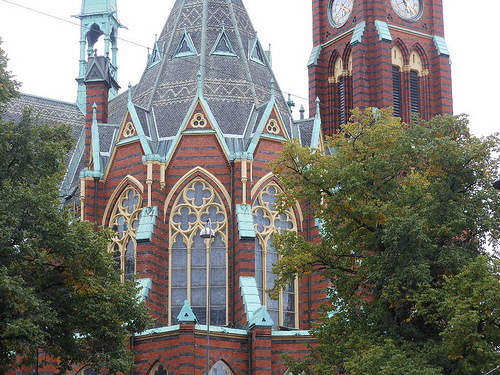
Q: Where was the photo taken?
A: It was taken at the church.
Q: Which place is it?
A: It is a church.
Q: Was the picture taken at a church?
A: Yes, it was taken in a church.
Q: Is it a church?
A: Yes, it is a church.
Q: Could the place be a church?
A: Yes, it is a church.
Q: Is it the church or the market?
A: It is the church.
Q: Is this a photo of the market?
A: No, the picture is showing the church.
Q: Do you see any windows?
A: Yes, there is a window.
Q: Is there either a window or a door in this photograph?
A: Yes, there is a window.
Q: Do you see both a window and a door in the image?
A: No, there is a window but no doors.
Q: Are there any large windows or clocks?
A: Yes, there is a large window.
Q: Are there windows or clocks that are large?
A: Yes, the window is large.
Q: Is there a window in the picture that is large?
A: Yes, there is a large window.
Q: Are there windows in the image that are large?
A: Yes, there is a window that is large.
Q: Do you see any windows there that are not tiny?
A: Yes, there is a large window.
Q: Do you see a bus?
A: No, there are no buses.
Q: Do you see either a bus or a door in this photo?
A: No, there are no buses or doors.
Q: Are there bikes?
A: No, there are no bikes.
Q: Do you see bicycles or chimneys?
A: No, there are no bicycles or chimneys.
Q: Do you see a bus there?
A: No, there are no buses.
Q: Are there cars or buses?
A: No, there are no buses or cars.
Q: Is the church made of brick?
A: Yes, the church is made of brick.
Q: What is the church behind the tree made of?
A: The church is made of brick.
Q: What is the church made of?
A: The church is made of brick.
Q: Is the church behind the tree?
A: Yes, the church is behind the tree.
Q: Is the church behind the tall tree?
A: Yes, the church is behind the tree.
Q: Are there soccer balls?
A: No, there are no soccer balls.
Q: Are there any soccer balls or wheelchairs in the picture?
A: No, there are no soccer balls or wheelchairs.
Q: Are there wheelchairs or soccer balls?
A: No, there are no soccer balls or wheelchairs.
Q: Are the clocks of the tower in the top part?
A: Yes, the clocks are in the top of the image.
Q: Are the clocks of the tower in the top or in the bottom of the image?
A: The clocks are in the top of the image.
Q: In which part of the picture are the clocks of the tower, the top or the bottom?
A: The clocks are in the top of the image.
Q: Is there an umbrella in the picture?
A: No, there are no umbrellas.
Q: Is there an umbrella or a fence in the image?
A: No, there are no umbrellas or fences.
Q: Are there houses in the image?
A: No, there are no houses.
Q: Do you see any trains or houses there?
A: No, there are no houses or trains.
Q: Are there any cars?
A: No, there are no cars.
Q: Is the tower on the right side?
A: Yes, the tower is on the right of the image.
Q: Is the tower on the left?
A: No, the tower is on the right of the image.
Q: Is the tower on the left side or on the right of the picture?
A: The tower is on the right of the image.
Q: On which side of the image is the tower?
A: The tower is on the right of the image.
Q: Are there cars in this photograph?
A: No, there are no cars.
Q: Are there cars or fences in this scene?
A: No, there are no cars or fences.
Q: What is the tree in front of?
A: The tree is in front of the church.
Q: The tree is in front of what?
A: The tree is in front of the church.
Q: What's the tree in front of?
A: The tree is in front of the church.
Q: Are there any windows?
A: Yes, there are windows.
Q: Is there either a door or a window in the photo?
A: Yes, there are windows.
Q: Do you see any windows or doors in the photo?
A: Yes, there are windows.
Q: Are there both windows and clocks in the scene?
A: Yes, there are both windows and a clock.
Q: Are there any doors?
A: No, there are no doors.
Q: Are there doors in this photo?
A: No, there are no doors.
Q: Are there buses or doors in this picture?
A: No, there are no doors or buses.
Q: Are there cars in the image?
A: No, there are no cars.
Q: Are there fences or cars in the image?
A: No, there are no cars or fences.